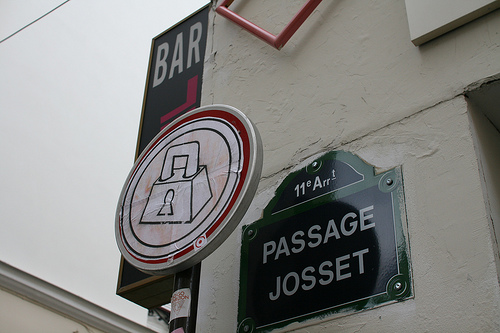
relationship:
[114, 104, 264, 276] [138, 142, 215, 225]
sign has a lock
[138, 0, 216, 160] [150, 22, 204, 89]
sign says bar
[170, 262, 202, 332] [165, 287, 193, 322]
pole has a sticker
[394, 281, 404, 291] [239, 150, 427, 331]
bolt on sign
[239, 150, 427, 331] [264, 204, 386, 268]
sign says passage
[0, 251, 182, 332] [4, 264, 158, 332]
roof has a gutter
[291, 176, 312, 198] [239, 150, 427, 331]
11e on sign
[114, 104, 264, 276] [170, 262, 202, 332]
sign on a pole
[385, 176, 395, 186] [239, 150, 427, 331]
fastener holding sign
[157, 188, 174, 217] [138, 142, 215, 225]
keyhole on lock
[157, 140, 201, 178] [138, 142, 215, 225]
handle on lock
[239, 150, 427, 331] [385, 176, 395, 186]
sign has a screw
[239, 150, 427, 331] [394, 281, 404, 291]
sign has a bottom right screw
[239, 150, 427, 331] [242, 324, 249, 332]
sign has a screw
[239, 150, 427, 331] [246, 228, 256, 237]
sign has a screw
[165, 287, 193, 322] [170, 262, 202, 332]
sticker on pole